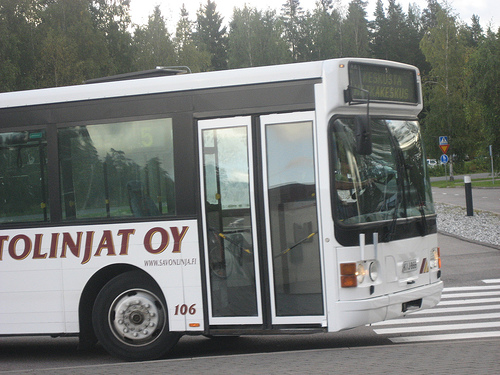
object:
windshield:
[327, 112, 435, 225]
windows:
[0, 114, 173, 224]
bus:
[0, 58, 445, 362]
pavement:
[0, 173, 499, 374]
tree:
[365, 0, 437, 82]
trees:
[0, 0, 117, 95]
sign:
[437, 135, 450, 165]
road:
[0, 170, 498, 372]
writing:
[0, 224, 189, 266]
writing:
[353, 69, 408, 86]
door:
[195, 109, 326, 334]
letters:
[0, 224, 189, 266]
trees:
[126, 0, 178, 75]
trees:
[189, 0, 226, 47]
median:
[433, 201, 499, 251]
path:
[433, 198, 500, 251]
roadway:
[0, 229, 498, 375]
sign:
[341, 61, 416, 102]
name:
[0, 225, 188, 265]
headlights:
[429, 248, 440, 280]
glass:
[56, 116, 178, 221]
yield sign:
[439, 143, 449, 153]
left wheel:
[91, 270, 179, 362]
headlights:
[339, 258, 378, 288]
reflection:
[60, 116, 174, 223]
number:
[174, 303, 198, 316]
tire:
[86, 268, 185, 363]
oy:
[142, 225, 189, 254]